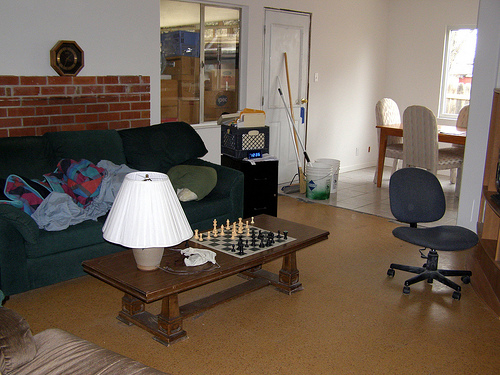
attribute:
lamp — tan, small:
[99, 168, 195, 276]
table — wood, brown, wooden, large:
[75, 205, 335, 352]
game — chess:
[188, 213, 299, 262]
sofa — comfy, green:
[1, 117, 246, 300]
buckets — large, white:
[314, 154, 342, 196]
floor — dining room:
[275, 156, 468, 234]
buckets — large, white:
[303, 161, 335, 204]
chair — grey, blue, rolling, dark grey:
[378, 167, 481, 303]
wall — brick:
[1, 73, 155, 149]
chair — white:
[449, 100, 472, 188]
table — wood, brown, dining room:
[371, 117, 472, 200]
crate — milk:
[215, 120, 273, 163]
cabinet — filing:
[219, 150, 282, 226]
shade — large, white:
[99, 170, 197, 253]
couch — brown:
[1, 301, 175, 374]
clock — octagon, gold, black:
[48, 36, 89, 80]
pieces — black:
[279, 229, 289, 241]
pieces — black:
[237, 242, 244, 257]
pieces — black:
[256, 239, 264, 251]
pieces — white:
[248, 215, 257, 224]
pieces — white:
[210, 217, 219, 232]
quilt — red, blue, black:
[2, 149, 110, 219]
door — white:
[260, 7, 313, 188]